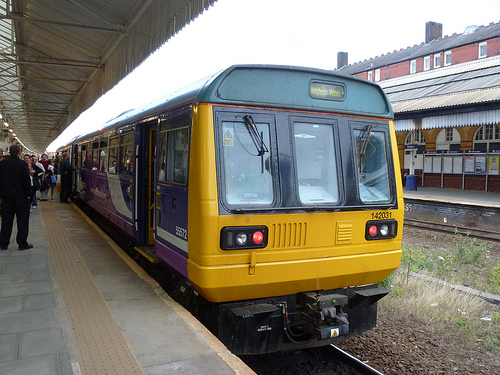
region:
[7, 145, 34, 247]
this is a person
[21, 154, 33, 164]
this is a person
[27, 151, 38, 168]
this is a person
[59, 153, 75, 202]
this is a person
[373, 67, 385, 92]
thi is is a window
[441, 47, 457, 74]
this is is a window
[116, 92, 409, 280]
the train is yellow and purple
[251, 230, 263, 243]
the light is red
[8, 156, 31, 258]
the man is dressed in black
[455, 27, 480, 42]
the roof is grey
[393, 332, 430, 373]
gravel is on the ground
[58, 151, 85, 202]
the man is about to board the bus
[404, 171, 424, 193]
the trash can is blue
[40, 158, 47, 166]
the shirt is red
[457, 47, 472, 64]
the wall is red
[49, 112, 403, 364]
the train is at the station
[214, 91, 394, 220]
the windshield wipers on the bus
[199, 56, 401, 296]
the front of the train is yellow and blue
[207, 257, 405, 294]
the bumper of the train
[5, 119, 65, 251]
people waiting for the train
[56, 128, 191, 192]
the windows on the train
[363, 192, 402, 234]
142031 is the train number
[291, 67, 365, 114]
this shows the next stop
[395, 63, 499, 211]
a store next to the train tracks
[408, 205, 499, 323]
train tracks on the ground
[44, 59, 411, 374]
A train pulling into a train station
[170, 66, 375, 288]
this is a train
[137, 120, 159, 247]
this is a door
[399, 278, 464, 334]
this is a grass area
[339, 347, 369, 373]
this is a metal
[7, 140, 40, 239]
this is a man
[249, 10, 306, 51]
tis is the sky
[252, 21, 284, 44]
the sky is blue in color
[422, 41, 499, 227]
this is a building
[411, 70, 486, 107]
this is the roof